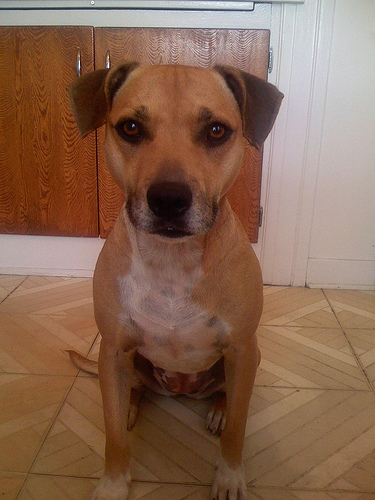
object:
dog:
[64, 61, 284, 499]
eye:
[118, 117, 148, 138]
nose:
[144, 180, 194, 218]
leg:
[208, 334, 261, 499]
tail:
[63, 348, 99, 376]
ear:
[212, 63, 284, 153]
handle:
[74, 48, 83, 80]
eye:
[198, 121, 230, 145]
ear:
[66, 61, 140, 140]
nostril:
[152, 194, 166, 215]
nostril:
[172, 192, 189, 210]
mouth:
[148, 221, 195, 241]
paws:
[209, 457, 249, 499]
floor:
[0, 273, 374, 499]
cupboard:
[0, 0, 283, 286]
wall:
[304, 0, 374, 291]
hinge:
[265, 48, 274, 76]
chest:
[121, 235, 219, 375]